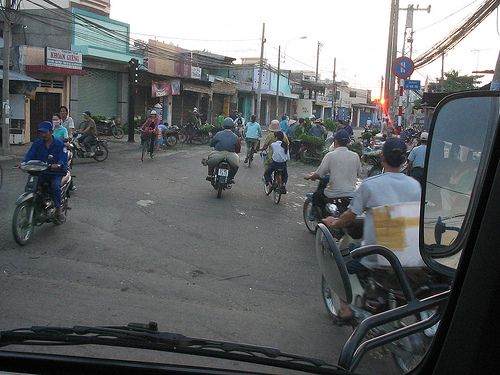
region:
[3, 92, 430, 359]
people in the street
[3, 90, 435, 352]
people on mopeds in the street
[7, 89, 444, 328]
people on bicycles in the street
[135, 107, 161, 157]
a person on a bicycle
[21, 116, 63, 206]
a man wearing blue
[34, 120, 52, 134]
a man wearing a blue hat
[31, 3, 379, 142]
store fronts on a street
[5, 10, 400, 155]
a shopping district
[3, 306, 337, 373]
a wiper on a window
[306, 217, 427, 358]
a mirror on a window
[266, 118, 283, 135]
pink hat on the person riding a bike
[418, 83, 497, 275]
black car side mirror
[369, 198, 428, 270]
brown and white bag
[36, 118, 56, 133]
blue hat on the person's head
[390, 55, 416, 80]
red and blue sign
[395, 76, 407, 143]
red and white striped pole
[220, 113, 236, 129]
gray helmet on the bicyclist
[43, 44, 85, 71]
white sign with red and blue letters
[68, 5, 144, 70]
dark and light green building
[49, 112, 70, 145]
woman wearing a blue shirt and pink face mask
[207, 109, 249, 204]
person riding a motorcycle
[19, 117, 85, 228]
person wearing blue hat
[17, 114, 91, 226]
person wearing blue clothing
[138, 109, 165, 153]
person wearing white hat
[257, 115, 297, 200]
person wearing a hat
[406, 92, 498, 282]
side mirror of a vehicle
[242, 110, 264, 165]
person wearing a blue jacket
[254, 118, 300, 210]
two person riding a bicycle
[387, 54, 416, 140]
traffic sign on the street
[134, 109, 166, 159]
person riding a bicycle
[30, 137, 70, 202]
the clothes are blue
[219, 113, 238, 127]
the helmet is grey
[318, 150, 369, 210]
the tshirt is grey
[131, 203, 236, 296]
the road is tarmced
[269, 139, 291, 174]
the girl is on a bike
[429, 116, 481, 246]
reflection is in the mirror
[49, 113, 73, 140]
she has a mask on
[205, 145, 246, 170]
luggage is on the bike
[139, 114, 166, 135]
the shirt is orange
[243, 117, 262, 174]
woman is riding a bike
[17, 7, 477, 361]
a busy city street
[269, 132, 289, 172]
a little with a ponytail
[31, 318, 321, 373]
a black metal windshield wiper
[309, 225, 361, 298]
a circular side view mirror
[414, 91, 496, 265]
a large oblong side view mirror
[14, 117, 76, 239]
a man riding a scooter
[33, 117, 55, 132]
a blue cap on a head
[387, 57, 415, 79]
a blue with red lines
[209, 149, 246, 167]
a large bundle on a scooter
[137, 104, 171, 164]
a woman riding a bicycle